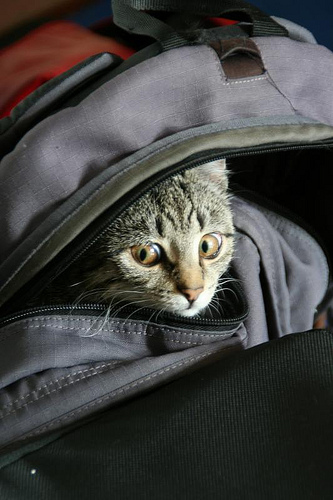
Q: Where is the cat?
A: In a backpack.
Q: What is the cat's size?
A: Small.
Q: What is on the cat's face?
A: Whiskers.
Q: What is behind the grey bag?
A: A red bag.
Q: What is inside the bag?
A: Cat.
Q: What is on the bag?
A: A handle.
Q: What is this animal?
A: Cat.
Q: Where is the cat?
A: In a bag.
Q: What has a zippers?
A: Bag.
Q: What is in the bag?
A: Cat.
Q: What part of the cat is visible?
A: The head.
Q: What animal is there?
A: A cat.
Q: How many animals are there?
A: One.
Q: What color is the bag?
A: Blue.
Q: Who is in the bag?
A: The cat.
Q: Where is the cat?
A: In the bag.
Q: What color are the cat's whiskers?
A: White.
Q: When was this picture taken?
A: After the cat was in the bag.